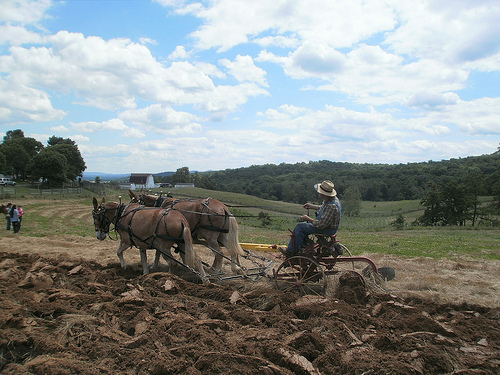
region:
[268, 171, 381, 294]
man being pulled by horses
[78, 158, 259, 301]
horses pulling a man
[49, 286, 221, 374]
a bunch of dirt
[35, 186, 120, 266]
the road the horses are on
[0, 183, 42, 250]
people looking in the distance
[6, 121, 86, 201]
trees in the background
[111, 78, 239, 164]
a beautiful blue sky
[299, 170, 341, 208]
a man wearing a hat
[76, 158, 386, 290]
two horses pulling a man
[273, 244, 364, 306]
wheels on the mans ride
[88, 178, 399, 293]
Man is riding horse drawn plough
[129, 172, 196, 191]
white barn house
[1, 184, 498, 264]
rolling green grass covered hills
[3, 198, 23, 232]
group of people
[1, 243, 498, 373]
freshly ploughed dark brown dirt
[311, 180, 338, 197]
tan brimmed hat on man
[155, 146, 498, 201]
tree covered hill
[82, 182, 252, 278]
two brown horses working side by side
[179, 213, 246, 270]
horses have blond tails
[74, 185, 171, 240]
horses are wearing bridles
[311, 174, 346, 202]
a straw hat with black detail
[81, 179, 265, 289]
two chestnut mules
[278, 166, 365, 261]
a farmer in overalls and plaid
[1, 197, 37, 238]
a group of people standing in field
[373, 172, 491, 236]
trees on the outskirt of a field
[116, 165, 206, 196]
a white farm house and barn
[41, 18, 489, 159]
blue sky with fluffy white clouds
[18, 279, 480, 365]
a freshly plowed field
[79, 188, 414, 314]
a red plow in motion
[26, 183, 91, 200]
a wooden fence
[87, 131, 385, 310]
Farmer, tilling with mule team.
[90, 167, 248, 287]
Matched brown mule team with lighter colored tails.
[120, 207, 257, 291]
Pale tails and legs on brown mules with black harness equipment.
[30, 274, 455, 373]
Rich, dark, well-tilled earth.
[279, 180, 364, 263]
Farmer in plaid shirt, hat and jeans, holding reins.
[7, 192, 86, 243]
People, standing in distance, observing well-tilled fields.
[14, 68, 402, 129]
Fluffy clouds in a bright blue sky.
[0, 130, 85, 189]
Healthy, bushy green trees.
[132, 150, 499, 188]
Buildings and green, rolling hills in distance.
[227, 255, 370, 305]
Elderly wheel of tilling equipment.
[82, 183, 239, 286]
two horses are seen.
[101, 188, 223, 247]
horses are brown in color.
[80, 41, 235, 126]
clouds are white in color.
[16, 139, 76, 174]
trees are green in color.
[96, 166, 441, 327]
horses are used to make furrow in the ground.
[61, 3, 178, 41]
sky is blue in color.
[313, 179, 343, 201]
man is wearing the hat.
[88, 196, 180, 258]
belt is black in color.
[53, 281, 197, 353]
ground is brown in color.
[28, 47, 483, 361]
daytime picture.